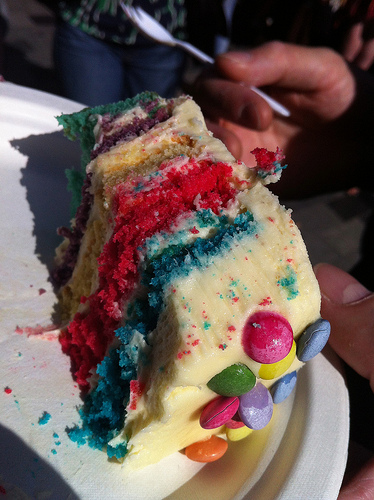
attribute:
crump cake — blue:
[26, 401, 54, 433]